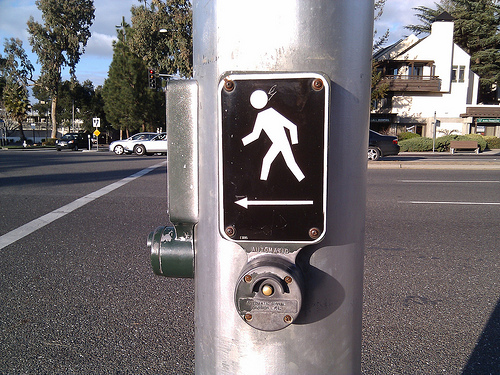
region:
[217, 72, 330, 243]
a black crosswalk sign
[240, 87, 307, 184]
a human walking figure on the sign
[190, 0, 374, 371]
a thick metal pole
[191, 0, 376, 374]
a crosswalk sign on a metal pole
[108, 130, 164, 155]
two white motor vehicles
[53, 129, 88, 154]
a stopped black car on the street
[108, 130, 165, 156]
two white cars on the street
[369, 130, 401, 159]
the backside of a black car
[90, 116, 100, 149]
two traffic signs on a pole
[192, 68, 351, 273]
The person is walking in the sign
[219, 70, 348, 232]
The person is white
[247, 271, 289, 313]
This is a button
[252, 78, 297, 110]
Writing on the sign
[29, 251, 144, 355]
This is the street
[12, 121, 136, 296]
White paint on the ground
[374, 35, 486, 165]
The house is white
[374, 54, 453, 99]
The porch is made of wood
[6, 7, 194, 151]
There are trees in the back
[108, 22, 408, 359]
a cross walk sign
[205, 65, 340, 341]
this sign is directing pedestrians to follow the arrow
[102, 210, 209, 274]
this light switch is green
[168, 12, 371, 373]
a shiny metal pole with traffic equipment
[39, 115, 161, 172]
traffic on the street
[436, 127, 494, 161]
a bench by the curb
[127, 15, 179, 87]
a street light above the area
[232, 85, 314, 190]
man walking symbol on a pole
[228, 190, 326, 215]
white arrow on a crosswalk sign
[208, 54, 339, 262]
a crosswalk sign on a pole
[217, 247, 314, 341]
a button to activate a crosswalk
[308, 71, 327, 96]
a rusty screw on a sign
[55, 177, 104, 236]
a white painted line on the pavement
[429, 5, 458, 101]
a chimney on the side of house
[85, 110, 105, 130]
a white and black road sign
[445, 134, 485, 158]
a brown bench by a bus stop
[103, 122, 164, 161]
cars moving along a street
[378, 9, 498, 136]
A white house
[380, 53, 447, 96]
The house has a balcony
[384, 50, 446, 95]
The balcony is made of wood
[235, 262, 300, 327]
Button to activate the crosswalk sign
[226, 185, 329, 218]
Arrow pointing to the left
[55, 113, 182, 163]
Cars driving on the road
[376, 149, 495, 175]
Median in the middle of the road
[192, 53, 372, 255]
A black and white sign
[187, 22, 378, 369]
The sign is on a metal pole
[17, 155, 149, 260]
A thick white line on the street